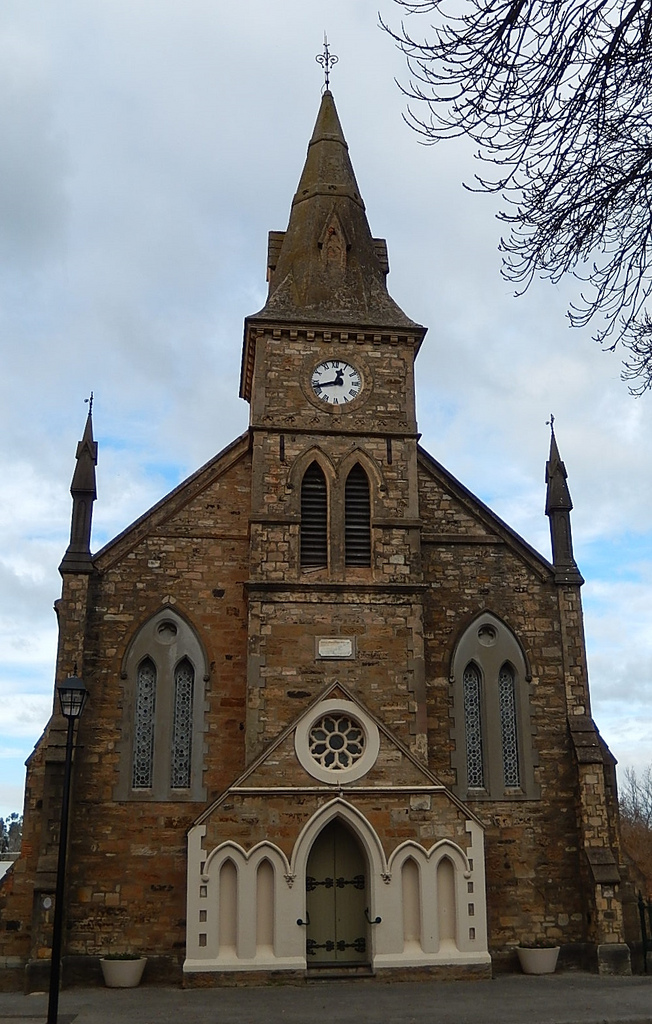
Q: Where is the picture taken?
A: Outside building.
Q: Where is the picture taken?
A: Outside a church.